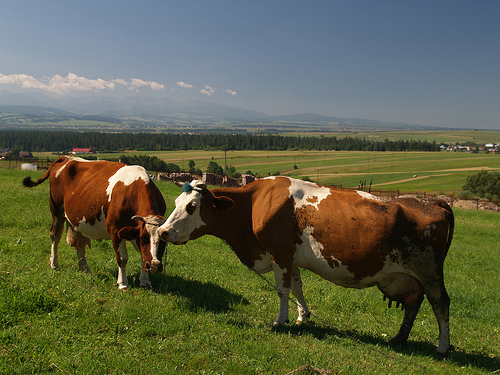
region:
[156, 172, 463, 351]
this is a cow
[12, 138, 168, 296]
this is a cow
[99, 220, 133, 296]
the leg of a cow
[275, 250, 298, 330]
the leg of a cow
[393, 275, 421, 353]
the leg of a cow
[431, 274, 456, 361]
the leg of a cow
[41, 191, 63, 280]
the leg of a cow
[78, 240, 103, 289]
the leg of a cow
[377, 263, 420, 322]
the udder of a cow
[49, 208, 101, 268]
the udder of a cow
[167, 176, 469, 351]
cow in the grass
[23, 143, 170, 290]
cow in the grass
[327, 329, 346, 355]
patch of green grass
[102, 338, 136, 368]
patch of green grass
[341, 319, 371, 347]
patch of green grass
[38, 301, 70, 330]
patch of green grass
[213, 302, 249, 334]
patch of green grass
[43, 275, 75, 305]
patch of green grass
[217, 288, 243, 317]
patch of green grass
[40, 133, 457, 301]
brown and white cows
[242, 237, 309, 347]
cow has white legs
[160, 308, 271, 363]
green grass under cow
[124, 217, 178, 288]
white streak on face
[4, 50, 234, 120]
small and puffy clouds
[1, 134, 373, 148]
green forest of trees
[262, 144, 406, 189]
green and brown field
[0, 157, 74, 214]
cow has long tail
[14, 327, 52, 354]
green grass on ground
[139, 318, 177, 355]
green grass on ground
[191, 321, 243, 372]
green grass on ground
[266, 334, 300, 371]
green grass on ground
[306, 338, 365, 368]
green grass on ground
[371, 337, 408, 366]
green grass on ground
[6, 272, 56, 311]
green grass on ground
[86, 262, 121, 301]
green grass on ground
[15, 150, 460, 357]
A pair of cow in a pasture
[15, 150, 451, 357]
A pair of cow in a pasture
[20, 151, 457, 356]
A pair of cow in a pasture